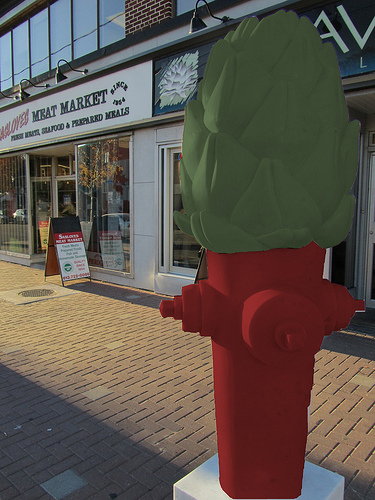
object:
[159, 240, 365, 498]
water pipe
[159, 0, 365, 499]
water pipe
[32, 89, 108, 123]
words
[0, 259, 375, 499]
sidewalk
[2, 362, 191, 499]
shade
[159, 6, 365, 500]
hydrant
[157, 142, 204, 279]
window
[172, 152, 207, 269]
reflection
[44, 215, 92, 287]
sign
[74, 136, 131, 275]
window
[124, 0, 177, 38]
brick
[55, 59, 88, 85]
light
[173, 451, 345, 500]
base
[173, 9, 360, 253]
artichoke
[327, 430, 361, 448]
brick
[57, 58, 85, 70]
pole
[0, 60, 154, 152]
sign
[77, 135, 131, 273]
reflection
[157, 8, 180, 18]
brick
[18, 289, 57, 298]
manhole cover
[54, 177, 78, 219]
door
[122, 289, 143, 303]
part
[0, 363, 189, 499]
edge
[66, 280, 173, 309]
part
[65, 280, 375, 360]
shade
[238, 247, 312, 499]
edge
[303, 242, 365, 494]
side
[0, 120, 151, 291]
store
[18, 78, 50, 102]
street lamp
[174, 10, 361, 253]
tree reflection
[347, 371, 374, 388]
brick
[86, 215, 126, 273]
car reflection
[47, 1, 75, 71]
window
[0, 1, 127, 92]
row